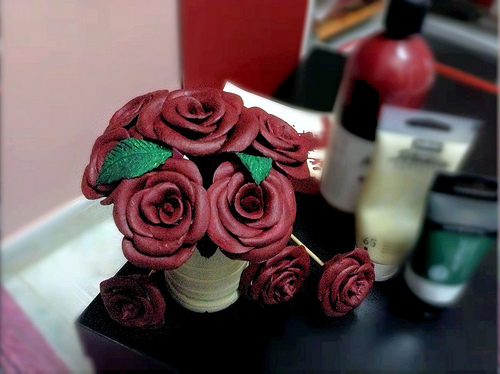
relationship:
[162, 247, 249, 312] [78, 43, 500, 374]
vase on black table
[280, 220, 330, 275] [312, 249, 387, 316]
stem on flower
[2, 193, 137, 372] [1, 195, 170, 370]
rug on floor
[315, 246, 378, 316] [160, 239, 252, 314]
rose in vase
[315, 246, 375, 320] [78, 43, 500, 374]
rose on black table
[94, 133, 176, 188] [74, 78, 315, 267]
leaf in bouquet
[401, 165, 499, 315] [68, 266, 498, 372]
tube on table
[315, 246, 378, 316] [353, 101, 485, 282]
rose molded lotion